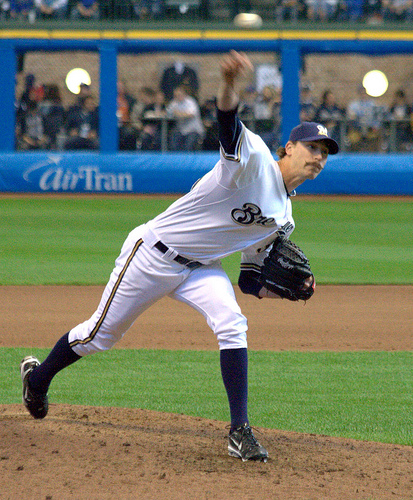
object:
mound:
[0, 401, 413, 500]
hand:
[292, 275, 316, 301]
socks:
[219, 348, 249, 434]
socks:
[28, 328, 81, 390]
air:
[261, 25, 412, 77]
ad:
[23, 155, 133, 191]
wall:
[0, 152, 413, 196]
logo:
[229, 201, 275, 228]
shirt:
[147, 120, 295, 275]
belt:
[153, 241, 203, 269]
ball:
[234, 12, 263, 28]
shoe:
[227, 421, 268, 463]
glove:
[279, 285, 314, 301]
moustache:
[304, 160, 322, 170]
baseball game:
[0, 0, 413, 500]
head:
[291, 141, 329, 181]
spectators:
[15, 52, 413, 152]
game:
[0, 0, 413, 495]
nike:
[229, 435, 243, 451]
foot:
[226, 422, 269, 462]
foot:
[20, 355, 50, 419]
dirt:
[0, 283, 412, 352]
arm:
[214, 72, 264, 170]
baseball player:
[18, 48, 340, 465]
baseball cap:
[289, 120, 340, 155]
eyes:
[306, 143, 318, 152]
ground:
[0, 347, 413, 500]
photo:
[0, 0, 413, 500]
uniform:
[26, 96, 296, 427]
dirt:
[2, 404, 411, 500]